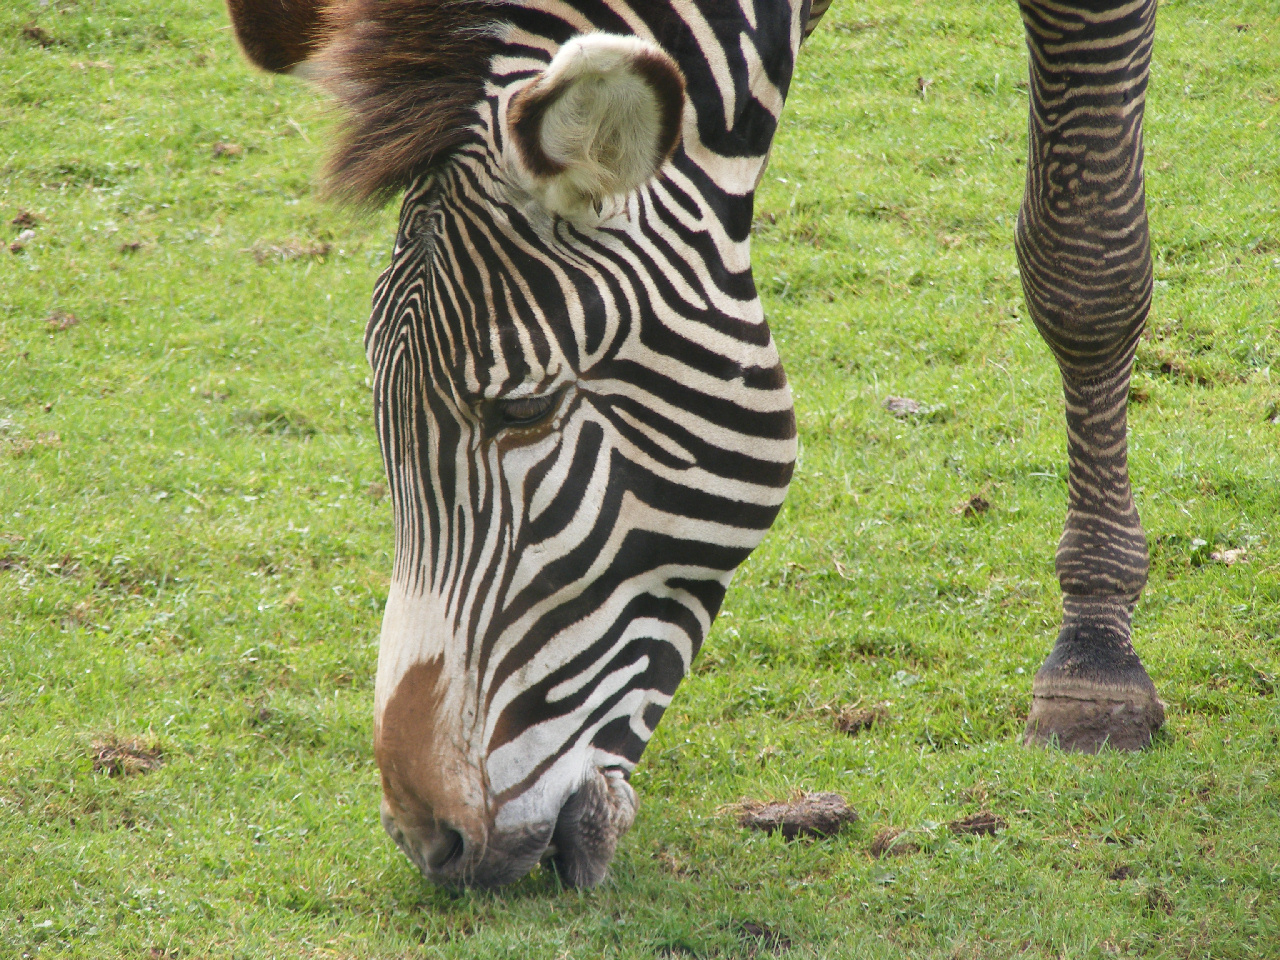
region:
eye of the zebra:
[440, 370, 606, 463]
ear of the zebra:
[504, 33, 699, 228]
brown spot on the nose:
[374, 637, 467, 816]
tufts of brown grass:
[725, 763, 851, 854]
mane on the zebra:
[325, 13, 458, 219]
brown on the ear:
[510, 88, 557, 181]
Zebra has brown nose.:
[379, 779, 512, 890]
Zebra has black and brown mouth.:
[527, 805, 622, 881]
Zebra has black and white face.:
[476, 531, 706, 691]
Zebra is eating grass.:
[408, 763, 676, 958]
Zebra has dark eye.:
[465, 353, 576, 448]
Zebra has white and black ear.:
[490, 33, 692, 192]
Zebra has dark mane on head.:
[315, 35, 481, 173]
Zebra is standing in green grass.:
[896, 648, 1210, 812]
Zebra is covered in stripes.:
[313, 161, 799, 784]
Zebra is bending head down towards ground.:
[271, 70, 843, 947]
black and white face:
[369, 157, 807, 906]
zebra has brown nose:
[321, 721, 412, 885]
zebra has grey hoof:
[987, 593, 1202, 819]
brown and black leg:
[987, 40, 1206, 559]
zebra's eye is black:
[453, 340, 621, 548]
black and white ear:
[497, 37, 676, 230]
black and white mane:
[285, 0, 442, 193]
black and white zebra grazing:
[296, 172, 877, 918]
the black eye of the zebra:
[486, 375, 568, 433]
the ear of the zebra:
[495, 24, 681, 205]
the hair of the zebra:
[301, 5, 496, 213]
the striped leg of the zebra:
[1014, 5, 1165, 747]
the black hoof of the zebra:
[1013, 695, 1173, 753]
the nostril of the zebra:
[422, 806, 471, 879]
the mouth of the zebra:
[532, 790, 597, 885]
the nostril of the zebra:
[382, 810, 427, 879]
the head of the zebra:
[356, 133, 804, 902]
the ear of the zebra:
[234, 4, 354, 106]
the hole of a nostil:
[434, 799, 472, 875]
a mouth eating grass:
[511, 755, 660, 914]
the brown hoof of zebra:
[1026, 671, 1197, 773]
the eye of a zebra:
[470, 353, 594, 460]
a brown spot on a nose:
[373, 609, 484, 859]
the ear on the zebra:
[470, 4, 729, 217]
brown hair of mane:
[300, 22, 510, 224]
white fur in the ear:
[558, 88, 645, 201]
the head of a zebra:
[291, 40, 863, 915]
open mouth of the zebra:
[505, 810, 589, 877]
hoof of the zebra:
[1028, 665, 1172, 747]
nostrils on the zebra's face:
[386, 803, 462, 881]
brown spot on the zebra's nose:
[362, 656, 468, 824]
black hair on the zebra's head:
[317, 14, 483, 195]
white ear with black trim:
[498, 22, 693, 217]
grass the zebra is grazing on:
[9, 11, 1278, 954]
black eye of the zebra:
[490, 373, 555, 435]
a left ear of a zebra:
[510, 28, 691, 210]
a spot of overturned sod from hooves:
[735, 785, 855, 839]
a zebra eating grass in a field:
[221, 4, 1166, 876]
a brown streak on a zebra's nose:
[371, 653, 491, 854]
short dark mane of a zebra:
[332, 11, 480, 208]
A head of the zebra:
[322, 302, 826, 878]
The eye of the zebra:
[445, 337, 616, 466]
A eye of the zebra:
[448, 342, 660, 482]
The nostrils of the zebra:
[361, 801, 496, 874]